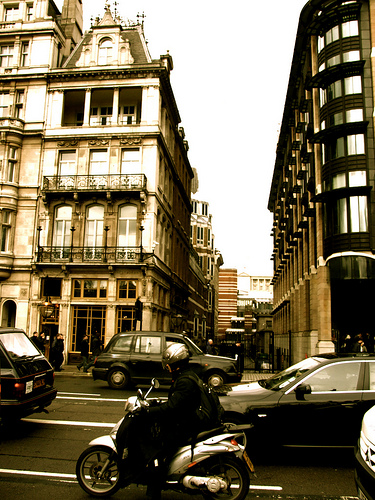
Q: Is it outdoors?
A: Yes, it is outdoors.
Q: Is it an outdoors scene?
A: Yes, it is outdoors.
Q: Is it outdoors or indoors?
A: It is outdoors.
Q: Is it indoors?
A: No, it is outdoors.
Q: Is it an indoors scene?
A: No, it is outdoors.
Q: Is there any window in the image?
A: Yes, there is a window.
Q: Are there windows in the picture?
A: Yes, there is a window.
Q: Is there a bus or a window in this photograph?
A: Yes, there is a window.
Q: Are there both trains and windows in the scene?
A: No, there is a window but no trains.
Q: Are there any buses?
A: No, there are no buses.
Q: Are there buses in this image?
A: No, there are no buses.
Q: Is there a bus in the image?
A: No, there are no buses.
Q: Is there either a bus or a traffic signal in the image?
A: No, there are no buses or traffic lights.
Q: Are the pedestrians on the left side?
A: Yes, the pedestrians are on the left of the image.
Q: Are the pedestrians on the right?
A: No, the pedestrians are on the left of the image.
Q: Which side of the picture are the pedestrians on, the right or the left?
A: The pedestrians are on the left of the image.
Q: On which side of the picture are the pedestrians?
A: The pedestrians are on the left of the image.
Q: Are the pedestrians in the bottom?
A: Yes, the pedestrians are in the bottom of the image.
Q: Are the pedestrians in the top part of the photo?
A: No, the pedestrians are in the bottom of the image.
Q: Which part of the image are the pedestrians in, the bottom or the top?
A: The pedestrians are in the bottom of the image.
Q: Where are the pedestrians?
A: The pedestrians are on the sidewalk.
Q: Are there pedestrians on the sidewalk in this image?
A: Yes, there are pedestrians on the sidewalk.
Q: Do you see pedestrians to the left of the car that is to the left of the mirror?
A: Yes, there are pedestrians to the left of the car.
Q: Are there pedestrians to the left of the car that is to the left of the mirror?
A: Yes, there are pedestrians to the left of the car.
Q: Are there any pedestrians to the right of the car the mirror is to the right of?
A: No, the pedestrians are to the left of the car.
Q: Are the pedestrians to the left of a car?
A: Yes, the pedestrians are to the left of a car.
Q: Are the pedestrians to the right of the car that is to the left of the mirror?
A: No, the pedestrians are to the left of the car.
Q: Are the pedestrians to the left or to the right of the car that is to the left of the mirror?
A: The pedestrians are to the left of the car.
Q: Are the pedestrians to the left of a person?
A: Yes, the pedestrians are to the left of a person.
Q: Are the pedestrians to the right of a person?
A: No, the pedestrians are to the left of a person.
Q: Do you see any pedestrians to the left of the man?
A: Yes, there are pedestrians to the left of the man.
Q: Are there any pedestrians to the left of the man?
A: Yes, there are pedestrians to the left of the man.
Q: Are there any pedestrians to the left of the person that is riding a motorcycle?
A: Yes, there are pedestrians to the left of the man.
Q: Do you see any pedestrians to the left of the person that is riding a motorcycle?
A: Yes, there are pedestrians to the left of the man.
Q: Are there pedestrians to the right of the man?
A: No, the pedestrians are to the left of the man.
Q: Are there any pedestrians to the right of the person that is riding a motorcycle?
A: No, the pedestrians are to the left of the man.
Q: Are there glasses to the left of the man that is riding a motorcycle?
A: No, there are pedestrians to the left of the man.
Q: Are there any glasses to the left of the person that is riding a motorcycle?
A: No, there are pedestrians to the left of the man.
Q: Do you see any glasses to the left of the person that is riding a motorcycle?
A: No, there are pedestrians to the left of the man.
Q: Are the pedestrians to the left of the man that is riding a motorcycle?
A: Yes, the pedestrians are to the left of the man.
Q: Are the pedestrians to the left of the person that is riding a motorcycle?
A: Yes, the pedestrians are to the left of the man.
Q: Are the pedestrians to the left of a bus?
A: No, the pedestrians are to the left of the man.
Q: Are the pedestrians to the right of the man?
A: No, the pedestrians are to the left of the man.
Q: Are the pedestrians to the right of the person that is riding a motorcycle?
A: No, the pedestrians are to the left of the man.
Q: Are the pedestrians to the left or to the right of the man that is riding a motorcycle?
A: The pedestrians are to the left of the man.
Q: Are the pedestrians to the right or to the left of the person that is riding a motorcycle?
A: The pedestrians are to the left of the man.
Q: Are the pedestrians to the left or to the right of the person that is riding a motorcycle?
A: The pedestrians are to the left of the man.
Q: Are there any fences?
A: No, there are no fences.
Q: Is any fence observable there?
A: No, there are no fences.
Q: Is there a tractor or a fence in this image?
A: No, there are no fences or tractors.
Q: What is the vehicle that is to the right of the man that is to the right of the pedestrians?
A: The vehicle is a car.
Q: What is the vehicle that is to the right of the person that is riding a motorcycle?
A: The vehicle is a car.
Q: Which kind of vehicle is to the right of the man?
A: The vehicle is a car.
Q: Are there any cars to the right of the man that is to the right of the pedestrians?
A: Yes, there is a car to the right of the man.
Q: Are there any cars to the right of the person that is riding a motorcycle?
A: Yes, there is a car to the right of the man.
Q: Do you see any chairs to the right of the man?
A: No, there is a car to the right of the man.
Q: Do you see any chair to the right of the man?
A: No, there is a car to the right of the man.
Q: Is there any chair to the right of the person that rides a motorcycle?
A: No, there is a car to the right of the man.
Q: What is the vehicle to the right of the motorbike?
A: The vehicle is a car.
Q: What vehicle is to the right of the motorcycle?
A: The vehicle is a car.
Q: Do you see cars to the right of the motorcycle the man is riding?
A: Yes, there is a car to the right of the motorbike.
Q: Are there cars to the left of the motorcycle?
A: No, the car is to the right of the motorcycle.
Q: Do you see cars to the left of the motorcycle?
A: No, the car is to the right of the motorcycle.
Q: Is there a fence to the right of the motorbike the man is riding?
A: No, there is a car to the right of the motorcycle.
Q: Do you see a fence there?
A: No, there are no fences.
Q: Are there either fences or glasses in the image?
A: No, there are no fences or glasses.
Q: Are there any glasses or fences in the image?
A: No, there are no fences or glasses.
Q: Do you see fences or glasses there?
A: No, there are no fences or glasses.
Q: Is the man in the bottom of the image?
A: Yes, the man is in the bottom of the image.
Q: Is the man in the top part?
A: No, the man is in the bottom of the image.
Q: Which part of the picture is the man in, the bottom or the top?
A: The man is in the bottom of the image.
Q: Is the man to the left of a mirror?
A: Yes, the man is to the left of a mirror.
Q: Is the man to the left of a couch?
A: No, the man is to the left of a mirror.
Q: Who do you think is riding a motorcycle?
A: The man is riding a motorcycle.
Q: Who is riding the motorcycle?
A: The man is riding a motorcycle.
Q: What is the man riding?
A: The man is riding a motorcycle.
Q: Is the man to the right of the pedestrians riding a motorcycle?
A: Yes, the man is riding a motorcycle.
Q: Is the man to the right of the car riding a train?
A: No, the man is riding a motorcycle.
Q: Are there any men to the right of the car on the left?
A: Yes, there is a man to the right of the car.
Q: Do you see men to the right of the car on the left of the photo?
A: Yes, there is a man to the right of the car.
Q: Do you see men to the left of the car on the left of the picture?
A: No, the man is to the right of the car.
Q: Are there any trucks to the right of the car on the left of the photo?
A: No, there is a man to the right of the car.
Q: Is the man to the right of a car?
A: Yes, the man is to the right of a car.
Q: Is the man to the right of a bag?
A: No, the man is to the right of a car.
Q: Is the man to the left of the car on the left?
A: No, the man is to the right of the car.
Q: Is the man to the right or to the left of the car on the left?
A: The man is to the right of the car.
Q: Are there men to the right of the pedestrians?
A: Yes, there is a man to the right of the pedestrians.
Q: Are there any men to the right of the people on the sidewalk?
A: Yes, there is a man to the right of the pedestrians.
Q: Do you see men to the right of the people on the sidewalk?
A: Yes, there is a man to the right of the pedestrians.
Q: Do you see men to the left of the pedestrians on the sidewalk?
A: No, the man is to the right of the pedestrians.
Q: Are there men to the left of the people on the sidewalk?
A: No, the man is to the right of the pedestrians.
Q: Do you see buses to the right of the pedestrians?
A: No, there is a man to the right of the pedestrians.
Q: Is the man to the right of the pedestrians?
A: Yes, the man is to the right of the pedestrians.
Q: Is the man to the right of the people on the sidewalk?
A: Yes, the man is to the right of the pedestrians.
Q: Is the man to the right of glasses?
A: No, the man is to the right of the pedestrians.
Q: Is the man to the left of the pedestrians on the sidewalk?
A: No, the man is to the right of the pedestrians.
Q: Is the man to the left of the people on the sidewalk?
A: No, the man is to the right of the pedestrians.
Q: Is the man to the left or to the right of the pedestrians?
A: The man is to the right of the pedestrians.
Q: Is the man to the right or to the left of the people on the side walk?
A: The man is to the right of the pedestrians.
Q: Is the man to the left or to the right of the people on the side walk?
A: The man is to the right of the pedestrians.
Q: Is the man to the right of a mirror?
A: No, the man is to the left of a mirror.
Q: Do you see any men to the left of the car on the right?
A: Yes, there is a man to the left of the car.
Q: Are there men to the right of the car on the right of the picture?
A: No, the man is to the left of the car.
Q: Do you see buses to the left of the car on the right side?
A: No, there is a man to the left of the car.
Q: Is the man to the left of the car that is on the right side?
A: Yes, the man is to the left of the car.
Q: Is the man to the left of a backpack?
A: No, the man is to the left of the car.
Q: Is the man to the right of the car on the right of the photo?
A: No, the man is to the left of the car.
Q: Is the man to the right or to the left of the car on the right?
A: The man is to the left of the car.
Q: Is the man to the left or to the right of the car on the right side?
A: The man is to the left of the car.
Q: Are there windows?
A: Yes, there is a window.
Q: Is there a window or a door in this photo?
A: Yes, there is a window.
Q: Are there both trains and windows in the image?
A: No, there is a window but no trains.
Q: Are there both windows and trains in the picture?
A: No, there is a window but no trains.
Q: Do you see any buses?
A: No, there are no buses.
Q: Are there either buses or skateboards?
A: No, there are no buses or skateboards.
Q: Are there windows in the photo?
A: Yes, there is a window.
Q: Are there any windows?
A: Yes, there is a window.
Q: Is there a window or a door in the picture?
A: Yes, there is a window.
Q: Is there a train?
A: No, there are no trains.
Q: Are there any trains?
A: No, there are no trains.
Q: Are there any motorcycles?
A: Yes, there is a motorcycle.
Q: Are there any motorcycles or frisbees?
A: Yes, there is a motorcycle.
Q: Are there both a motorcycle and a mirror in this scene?
A: Yes, there are both a motorcycle and a mirror.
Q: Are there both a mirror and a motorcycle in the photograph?
A: Yes, there are both a motorcycle and a mirror.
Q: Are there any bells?
A: No, there are no bells.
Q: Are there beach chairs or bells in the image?
A: No, there are no bells or beach chairs.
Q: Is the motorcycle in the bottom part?
A: Yes, the motorcycle is in the bottom of the image.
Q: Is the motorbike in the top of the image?
A: No, the motorbike is in the bottom of the image.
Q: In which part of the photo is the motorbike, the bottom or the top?
A: The motorbike is in the bottom of the image.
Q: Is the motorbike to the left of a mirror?
A: Yes, the motorbike is to the left of a mirror.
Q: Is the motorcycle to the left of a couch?
A: No, the motorcycle is to the left of a mirror.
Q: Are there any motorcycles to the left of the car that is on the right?
A: Yes, there is a motorcycle to the left of the car.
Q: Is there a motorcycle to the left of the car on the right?
A: Yes, there is a motorcycle to the left of the car.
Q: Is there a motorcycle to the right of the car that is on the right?
A: No, the motorcycle is to the left of the car.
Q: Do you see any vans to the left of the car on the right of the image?
A: No, there is a motorcycle to the left of the car.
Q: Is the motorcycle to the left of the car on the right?
A: Yes, the motorcycle is to the left of the car.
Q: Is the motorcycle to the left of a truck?
A: No, the motorcycle is to the left of the car.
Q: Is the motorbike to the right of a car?
A: No, the motorbike is to the left of a car.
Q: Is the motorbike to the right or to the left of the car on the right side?
A: The motorbike is to the left of the car.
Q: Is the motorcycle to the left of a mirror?
A: Yes, the motorcycle is to the left of a mirror.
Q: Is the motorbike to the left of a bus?
A: No, the motorbike is to the left of a mirror.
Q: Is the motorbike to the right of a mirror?
A: No, the motorbike is to the left of a mirror.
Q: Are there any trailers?
A: No, there are no trailers.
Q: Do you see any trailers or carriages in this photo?
A: No, there are no trailers or carriages.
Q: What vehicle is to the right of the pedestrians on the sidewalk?
A: The vehicle is a car.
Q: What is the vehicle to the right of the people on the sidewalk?
A: The vehicle is a car.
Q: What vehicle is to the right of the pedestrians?
A: The vehicle is a car.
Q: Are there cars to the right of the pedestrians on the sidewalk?
A: Yes, there is a car to the right of the pedestrians.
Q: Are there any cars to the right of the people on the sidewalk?
A: Yes, there is a car to the right of the pedestrians.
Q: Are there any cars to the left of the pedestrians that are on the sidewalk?
A: No, the car is to the right of the pedestrians.